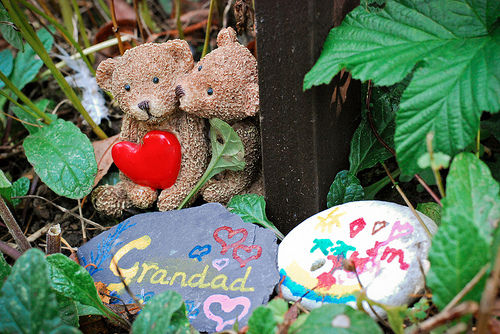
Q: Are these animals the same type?
A: Yes, all the animals are bears.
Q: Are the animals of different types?
A: No, all the animals are bears.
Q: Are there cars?
A: No, there are no cars.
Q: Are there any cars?
A: No, there are no cars.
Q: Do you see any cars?
A: No, there are no cars.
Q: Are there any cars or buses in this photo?
A: No, there are no cars or buses.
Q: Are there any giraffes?
A: No, there are no giraffes.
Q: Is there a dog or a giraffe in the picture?
A: No, there are no giraffes or dogs.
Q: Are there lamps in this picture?
A: No, there are no lamps.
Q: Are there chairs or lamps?
A: No, there are no lamps or chairs.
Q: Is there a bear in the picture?
A: Yes, there is a bear.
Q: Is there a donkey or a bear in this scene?
A: Yes, there is a bear.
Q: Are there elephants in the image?
A: No, there are no elephants.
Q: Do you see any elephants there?
A: No, there are no elephants.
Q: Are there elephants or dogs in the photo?
A: No, there are no elephants or dogs.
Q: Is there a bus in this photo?
A: No, there are no buses.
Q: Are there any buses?
A: No, there are no buses.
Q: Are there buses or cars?
A: No, there are no buses or cars.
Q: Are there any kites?
A: No, there are no kites.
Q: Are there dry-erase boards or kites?
A: No, there are no kites or dry-erase boards.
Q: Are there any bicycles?
A: No, there are no bicycles.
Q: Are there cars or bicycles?
A: No, there are no bicycles or cars.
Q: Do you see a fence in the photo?
A: No, there are no fences.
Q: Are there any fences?
A: No, there are no fences.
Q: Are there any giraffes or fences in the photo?
A: No, there are no fences or giraffes.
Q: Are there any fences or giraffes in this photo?
A: No, there are no fences or giraffes.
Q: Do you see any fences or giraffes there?
A: No, there are no fences or giraffes.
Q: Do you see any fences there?
A: No, there are no fences.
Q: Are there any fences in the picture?
A: No, there are no fences.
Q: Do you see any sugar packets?
A: No, there are no sugar packets.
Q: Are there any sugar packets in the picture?
A: No, there are no sugar packets.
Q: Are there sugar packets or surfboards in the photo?
A: No, there are no sugar packets or surfboards.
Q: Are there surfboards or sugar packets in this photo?
A: No, there are no sugar packets or surfboards.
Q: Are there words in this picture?
A: Yes, there are words.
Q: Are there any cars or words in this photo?
A: Yes, there are words.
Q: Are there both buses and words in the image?
A: No, there are words but no buses.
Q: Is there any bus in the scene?
A: No, there are no buses.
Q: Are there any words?
A: Yes, there are words.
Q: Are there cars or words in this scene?
A: Yes, there are words.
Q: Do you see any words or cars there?
A: Yes, there are words.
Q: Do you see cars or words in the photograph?
A: Yes, there are words.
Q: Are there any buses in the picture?
A: No, there are no buses.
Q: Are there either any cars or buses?
A: No, there are no buses or cars.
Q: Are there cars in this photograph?
A: No, there are no cars.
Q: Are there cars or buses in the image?
A: No, there are no cars or buses.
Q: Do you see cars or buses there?
A: No, there are no buses or cars.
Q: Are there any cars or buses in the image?
A: No, there are no cars or buses.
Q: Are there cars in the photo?
A: No, there are no cars.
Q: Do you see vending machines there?
A: No, there are no vending machines.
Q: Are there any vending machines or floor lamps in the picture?
A: No, there are no vending machines or floor lamps.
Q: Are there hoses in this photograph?
A: No, there are no hoses.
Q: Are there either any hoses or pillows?
A: No, there are no hoses or pillows.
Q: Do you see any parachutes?
A: No, there are no parachutes.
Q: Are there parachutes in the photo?
A: No, there are no parachutes.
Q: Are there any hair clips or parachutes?
A: No, there are no parachutes or hair clips.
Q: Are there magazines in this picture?
A: No, there are no magazines.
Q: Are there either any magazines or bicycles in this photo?
A: No, there are no magazines or bicycles.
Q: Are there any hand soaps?
A: No, there are no hand soaps.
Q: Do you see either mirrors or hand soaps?
A: No, there are no hand soaps or mirrors.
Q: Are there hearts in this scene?
A: Yes, there is a heart.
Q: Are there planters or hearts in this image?
A: Yes, there is a heart.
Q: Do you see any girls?
A: No, there are no girls.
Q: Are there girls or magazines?
A: No, there are no girls or magazines.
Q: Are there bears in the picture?
A: Yes, there is a bear.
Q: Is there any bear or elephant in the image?
A: Yes, there is a bear.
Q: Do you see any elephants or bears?
A: Yes, there is a bear.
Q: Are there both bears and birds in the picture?
A: No, there is a bear but no birds.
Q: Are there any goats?
A: No, there are no goats.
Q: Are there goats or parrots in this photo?
A: No, there are no goats or parrots.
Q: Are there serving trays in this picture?
A: No, there are no serving trays.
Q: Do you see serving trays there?
A: No, there are no serving trays.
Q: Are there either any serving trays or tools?
A: No, there are no serving trays or tools.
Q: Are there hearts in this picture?
A: Yes, there is a heart.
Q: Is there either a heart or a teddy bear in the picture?
A: Yes, there is a heart.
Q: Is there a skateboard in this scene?
A: No, there are no skateboards.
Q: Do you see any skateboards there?
A: No, there are no skateboards.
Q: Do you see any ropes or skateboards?
A: No, there are no skateboards or ropes.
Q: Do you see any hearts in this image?
A: Yes, there is a heart.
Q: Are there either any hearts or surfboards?
A: Yes, there is a heart.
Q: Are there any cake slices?
A: No, there are no cake slices.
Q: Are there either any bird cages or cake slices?
A: No, there are no cake slices or bird cages.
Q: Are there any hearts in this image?
A: Yes, there is a heart.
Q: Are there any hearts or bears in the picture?
A: Yes, there is a heart.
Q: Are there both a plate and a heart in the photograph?
A: No, there is a heart but no plates.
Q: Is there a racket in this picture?
A: No, there are no rackets.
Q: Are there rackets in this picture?
A: No, there are no rackets.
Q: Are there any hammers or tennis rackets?
A: No, there are no tennis rackets or hammers.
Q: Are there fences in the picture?
A: No, there are no fences.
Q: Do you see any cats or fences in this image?
A: No, there are no fences or cats.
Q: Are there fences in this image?
A: No, there are no fences.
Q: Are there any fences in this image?
A: No, there are no fences.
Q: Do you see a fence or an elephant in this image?
A: No, there are no fences or elephants.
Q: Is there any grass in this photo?
A: Yes, there is grass.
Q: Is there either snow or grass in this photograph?
A: Yes, there is grass.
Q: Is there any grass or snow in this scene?
A: Yes, there is grass.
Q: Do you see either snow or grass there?
A: Yes, there is grass.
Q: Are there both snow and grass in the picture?
A: No, there is grass but no snow.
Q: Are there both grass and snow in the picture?
A: No, there is grass but no snow.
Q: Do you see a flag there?
A: No, there are no flags.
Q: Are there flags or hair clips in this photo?
A: No, there are no flags or hair clips.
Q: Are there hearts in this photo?
A: Yes, there is a heart.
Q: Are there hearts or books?
A: Yes, there is a heart.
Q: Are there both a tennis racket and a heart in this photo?
A: No, there is a heart but no rackets.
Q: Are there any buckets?
A: No, there are no buckets.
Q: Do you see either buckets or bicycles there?
A: No, there are no buckets or bicycles.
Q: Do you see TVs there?
A: No, there are no tvs.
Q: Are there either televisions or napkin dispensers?
A: No, there are no televisions or napkin dispensers.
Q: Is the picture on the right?
A: Yes, the picture is on the right of the image.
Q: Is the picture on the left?
A: No, the picture is on the right of the image.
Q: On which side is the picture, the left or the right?
A: The picture is on the right of the image.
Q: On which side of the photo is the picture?
A: The picture is on the right of the image.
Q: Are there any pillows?
A: No, there are no pillows.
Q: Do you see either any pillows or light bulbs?
A: No, there are no pillows or light bulbs.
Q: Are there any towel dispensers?
A: No, there are no towel dispensers.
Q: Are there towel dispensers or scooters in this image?
A: No, there are no towel dispensers or scooters.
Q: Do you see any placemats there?
A: No, there are no placemats.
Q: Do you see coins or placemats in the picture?
A: No, there are no placemats or coins.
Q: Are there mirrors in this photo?
A: No, there are no mirrors.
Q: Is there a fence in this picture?
A: No, there are no fences.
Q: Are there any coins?
A: No, there are no coins.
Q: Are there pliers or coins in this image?
A: No, there are no coins or pliers.